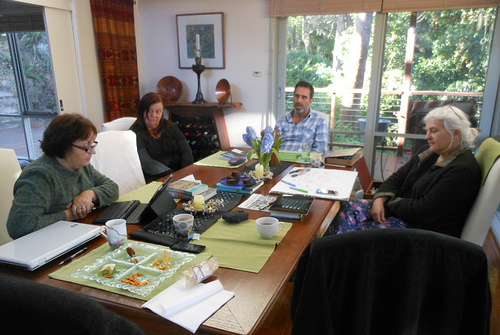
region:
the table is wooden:
[83, 123, 268, 322]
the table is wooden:
[152, 159, 328, 329]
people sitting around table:
[1, 54, 492, 334]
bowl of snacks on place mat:
[70, 237, 207, 311]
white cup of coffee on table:
[243, 202, 295, 254]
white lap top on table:
[0, 197, 118, 285]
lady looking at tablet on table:
[0, 100, 187, 249]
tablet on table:
[269, 163, 313, 225]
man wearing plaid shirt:
[261, 60, 333, 170]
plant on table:
[235, 123, 302, 197]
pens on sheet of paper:
[280, 162, 347, 220]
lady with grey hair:
[402, 82, 481, 172]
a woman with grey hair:
[420, 97, 475, 165]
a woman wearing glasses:
[59, 112, 99, 169]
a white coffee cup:
[236, 211, 291, 250]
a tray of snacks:
[69, 243, 199, 311]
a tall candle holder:
[190, 32, 205, 114]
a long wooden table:
[143, 122, 357, 333]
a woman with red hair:
[139, 80, 179, 138]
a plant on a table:
[236, 119, 283, 194]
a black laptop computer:
[73, 165, 175, 235]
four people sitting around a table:
[3, 63, 486, 333]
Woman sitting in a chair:
[347, 99, 482, 230]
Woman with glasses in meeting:
[1, 106, 128, 229]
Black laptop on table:
[114, 170, 184, 232]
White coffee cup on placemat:
[253, 209, 291, 248]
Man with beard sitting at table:
[276, 79, 328, 162]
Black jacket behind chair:
[297, 216, 498, 333]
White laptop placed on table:
[11, 209, 98, 291]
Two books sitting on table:
[173, 176, 215, 201]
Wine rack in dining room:
[177, 102, 236, 155]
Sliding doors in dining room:
[258, 1, 498, 83]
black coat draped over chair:
[288, 226, 490, 329]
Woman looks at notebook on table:
[39, 113, 176, 231]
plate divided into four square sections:
[93, 231, 185, 298]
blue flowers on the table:
[236, 119, 283, 181]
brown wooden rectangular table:
[11, 140, 348, 334]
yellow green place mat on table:
[181, 208, 293, 270]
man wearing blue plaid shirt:
[261, 79, 334, 155]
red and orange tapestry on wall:
[91, 1, 140, 117]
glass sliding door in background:
[0, 0, 58, 170]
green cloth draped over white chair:
[477, 129, 499, 197]